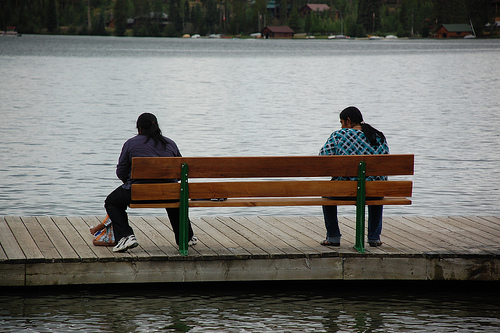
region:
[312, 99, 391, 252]
a woman sitting on a bench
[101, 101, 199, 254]
a woman with a navy shirt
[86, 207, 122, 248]
a bag at a woman's feet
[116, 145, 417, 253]
a wood bench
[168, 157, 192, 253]
a green metal support on a wooden bench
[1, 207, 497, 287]
a wood walkway over the water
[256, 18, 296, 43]
a cabin on the other side of the water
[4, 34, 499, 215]
a placid body of water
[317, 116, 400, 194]
a blue and black plaid shirt on a woman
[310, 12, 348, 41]
trees on the edge of the water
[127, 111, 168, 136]
Woman has black hair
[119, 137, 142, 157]
Woman wears purple shirt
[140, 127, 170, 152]
Woman's hair is long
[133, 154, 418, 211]
Back of brown bench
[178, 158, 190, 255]
Green pole in back of bench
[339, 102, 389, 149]
Woman has ponytail in hair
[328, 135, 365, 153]
Woman wears plaid shirt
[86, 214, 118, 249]
Multicolored bag on deck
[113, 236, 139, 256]
Woman wears black and white sneakers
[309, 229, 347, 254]
Woman wears grey sandals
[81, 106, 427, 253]
two people sitting on a bench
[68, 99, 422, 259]
two people on a bench by a pier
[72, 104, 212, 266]
sitting on a bench by the water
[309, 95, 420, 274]
sitting on the bench on the pier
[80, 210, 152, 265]
sack on the pier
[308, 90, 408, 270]
women in sandals with a pony tail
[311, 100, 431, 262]
woman in a blue striped shirt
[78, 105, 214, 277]
person in a blue shirt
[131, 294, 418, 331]
ripples and reflections in the water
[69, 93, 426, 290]
sitting on a pier in the water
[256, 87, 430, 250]
A bench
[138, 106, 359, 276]
A bench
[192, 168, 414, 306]
A bench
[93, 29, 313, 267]
A bench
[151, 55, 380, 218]
A bench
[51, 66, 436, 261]
two people sitting on a bench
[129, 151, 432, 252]
wooden bench on a dock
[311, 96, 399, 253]
woman wearing a blue checkered shirt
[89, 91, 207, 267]
woman wearing a black shirt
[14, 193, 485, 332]
wooden dock on water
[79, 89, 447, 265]
two women sitting on a wooden bench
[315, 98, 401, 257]
woman with a ponytail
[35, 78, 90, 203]
water of a lake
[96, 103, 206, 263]
woman wearing black pants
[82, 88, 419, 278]
two women on a dock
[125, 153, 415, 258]
bench that two people are sitting on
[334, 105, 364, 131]
Head of a woman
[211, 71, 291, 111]
Large body of water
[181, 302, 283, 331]
Large body of water